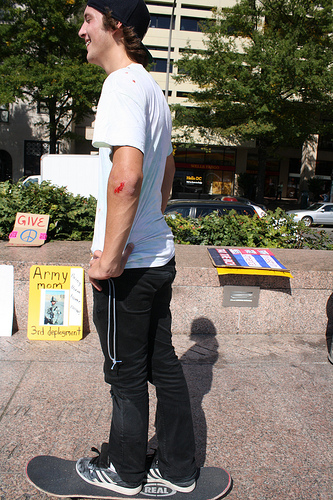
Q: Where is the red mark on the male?
A: On his elbow.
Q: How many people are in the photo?
A: One.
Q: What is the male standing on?
A: Skateboard.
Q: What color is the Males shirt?
A: White.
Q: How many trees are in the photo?
A: Two.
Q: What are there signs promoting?
A: Peace.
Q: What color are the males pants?
A: Black.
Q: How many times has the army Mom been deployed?
A: Three.